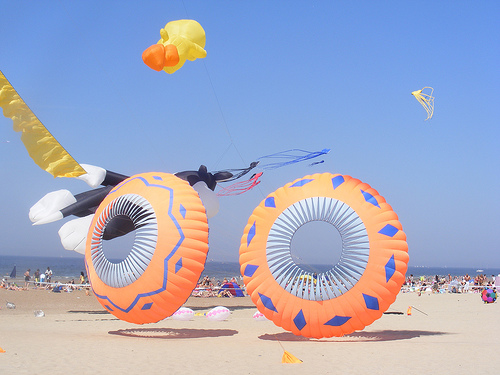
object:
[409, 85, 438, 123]
kite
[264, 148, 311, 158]
streamer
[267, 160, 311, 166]
streamer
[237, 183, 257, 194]
streamer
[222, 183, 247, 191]
streamer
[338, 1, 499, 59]
sky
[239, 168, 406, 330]
kite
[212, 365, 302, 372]
beach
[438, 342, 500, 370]
sand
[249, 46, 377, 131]
sky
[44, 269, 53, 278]
shirt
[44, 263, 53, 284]
person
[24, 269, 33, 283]
person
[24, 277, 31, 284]
shorts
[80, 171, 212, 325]
kites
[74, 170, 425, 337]
these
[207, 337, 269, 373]
sand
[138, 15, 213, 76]
air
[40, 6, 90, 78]
sky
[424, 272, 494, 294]
beach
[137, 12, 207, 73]
bird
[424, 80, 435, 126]
tails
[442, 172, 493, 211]
clouds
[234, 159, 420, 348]
kite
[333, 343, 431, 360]
ground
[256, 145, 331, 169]
kite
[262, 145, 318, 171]
tails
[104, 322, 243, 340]
shadow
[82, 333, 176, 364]
ground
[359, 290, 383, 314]
shape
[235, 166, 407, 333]
kite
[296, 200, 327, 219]
pattern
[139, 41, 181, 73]
feet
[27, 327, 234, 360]
sand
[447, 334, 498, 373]
beach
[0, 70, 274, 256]
kite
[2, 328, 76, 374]
beach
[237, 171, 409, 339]
kite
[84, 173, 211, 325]
kite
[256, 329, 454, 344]
shadow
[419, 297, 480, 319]
ground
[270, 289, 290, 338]
line